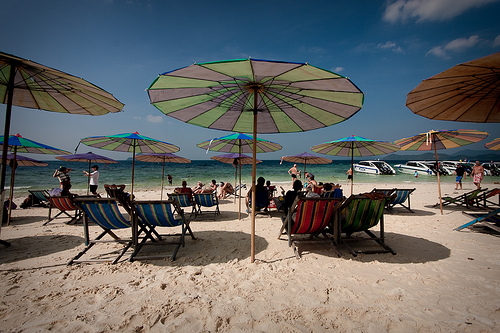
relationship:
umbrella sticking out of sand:
[145, 52, 369, 267] [0, 179, 499, 330]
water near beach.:
[23, 133, 495, 189] [5, 150, 493, 329]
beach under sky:
[284, 256, 421, 331] [1, 1, 488, 156]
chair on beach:
[334, 190, 395, 256] [3, 169, 496, 331]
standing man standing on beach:
[284, 158, 299, 183] [0, 144, 497, 331]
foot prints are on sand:
[116, 266, 222, 311] [24, 260, 314, 331]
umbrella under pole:
[145, 52, 370, 137] [249, 72, 261, 264]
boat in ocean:
[350, 156, 396, 178] [3, 158, 495, 180]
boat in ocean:
[391, 156, 448, 176] [5, 152, 478, 167]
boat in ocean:
[440, 158, 477, 173] [0, 154, 500, 197]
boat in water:
[350, 156, 399, 178] [0, 133, 500, 189]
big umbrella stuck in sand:
[139, 61, 399, 232] [4, 223, 497, 330]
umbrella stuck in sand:
[196, 131, 279, 215] [152, 187, 321, 331]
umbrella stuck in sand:
[307, 132, 402, 196] [338, 188, 489, 329]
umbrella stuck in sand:
[397, 120, 497, 175] [367, 177, 494, 330]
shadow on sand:
[128, 227, 270, 269] [4, 223, 497, 330]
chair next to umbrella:
[127, 192, 203, 254] [145, 52, 369, 267]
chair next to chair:
[341, 190, 396, 256] [278, 194, 345, 256]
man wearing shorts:
[468, 158, 487, 193] [470, 172, 485, 183]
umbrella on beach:
[0, 50, 130, 222] [3, 169, 496, 331]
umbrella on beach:
[0, 129, 62, 194] [3, 169, 496, 331]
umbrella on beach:
[1, 155, 52, 231] [3, 169, 496, 331]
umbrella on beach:
[57, 150, 118, 181] [3, 169, 496, 331]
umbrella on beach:
[76, 128, 182, 196] [3, 169, 496, 331]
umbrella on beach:
[131, 148, 191, 188] [3, 169, 496, 331]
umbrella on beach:
[211, 152, 266, 185] [3, 169, 496, 331]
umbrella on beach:
[199, 132, 281, 191] [3, 169, 496, 331]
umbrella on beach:
[145, 52, 369, 267] [3, 169, 496, 331]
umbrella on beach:
[286, 147, 329, 176] [3, 169, 496, 331]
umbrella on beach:
[307, 132, 402, 196] [3, 169, 496, 331]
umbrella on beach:
[393, 122, 490, 210] [3, 169, 496, 331]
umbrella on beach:
[401, 45, 499, 127] [3, 169, 496, 331]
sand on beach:
[9, 265, 495, 331] [3, 169, 496, 331]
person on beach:
[52, 162, 73, 195] [11, 179, 473, 321]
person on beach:
[82, 163, 100, 197] [11, 179, 473, 321]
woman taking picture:
[78, 160, 103, 194] [1, 1, 497, 328]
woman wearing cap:
[78, 160, 102, 198] [87, 163, 100, 172]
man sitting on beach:
[247, 176, 271, 216] [3, 169, 496, 331]